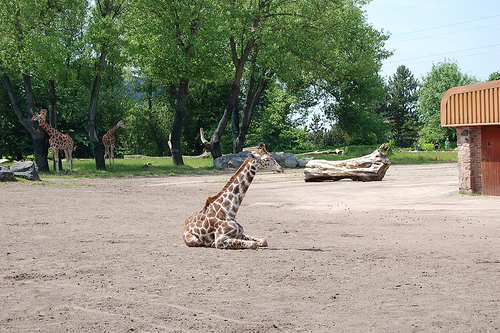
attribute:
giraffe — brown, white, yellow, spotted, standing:
[28, 104, 83, 173]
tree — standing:
[0, 2, 89, 178]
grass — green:
[26, 154, 189, 179]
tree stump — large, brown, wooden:
[296, 144, 403, 186]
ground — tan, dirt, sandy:
[97, 147, 474, 332]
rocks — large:
[206, 141, 312, 179]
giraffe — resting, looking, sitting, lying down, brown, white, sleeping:
[170, 138, 288, 257]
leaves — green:
[12, 10, 310, 87]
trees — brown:
[1, 1, 273, 165]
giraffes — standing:
[21, 104, 144, 176]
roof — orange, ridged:
[434, 86, 498, 125]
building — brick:
[439, 79, 500, 192]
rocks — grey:
[2, 159, 41, 189]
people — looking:
[424, 129, 459, 157]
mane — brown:
[206, 148, 259, 195]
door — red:
[480, 127, 499, 194]